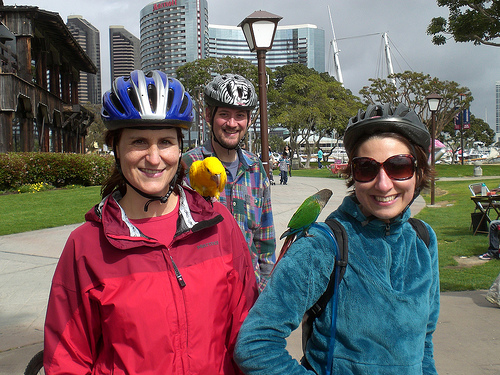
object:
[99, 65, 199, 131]
helmet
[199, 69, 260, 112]
helmet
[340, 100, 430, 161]
helmet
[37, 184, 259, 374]
jacket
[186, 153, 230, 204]
bird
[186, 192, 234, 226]
shoulder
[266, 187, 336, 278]
bird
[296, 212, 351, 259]
shoulder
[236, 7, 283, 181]
lamp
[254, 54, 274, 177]
post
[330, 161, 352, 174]
table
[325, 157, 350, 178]
picnic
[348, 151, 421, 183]
sunglasses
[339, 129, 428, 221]
head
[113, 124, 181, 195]
head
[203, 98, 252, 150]
head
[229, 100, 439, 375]
woman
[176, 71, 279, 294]
man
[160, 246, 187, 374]
zipper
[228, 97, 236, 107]
black stripes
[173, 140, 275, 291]
shirt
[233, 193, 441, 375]
jacket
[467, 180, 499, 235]
chair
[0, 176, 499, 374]
road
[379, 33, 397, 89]
mast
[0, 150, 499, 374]
park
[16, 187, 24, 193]
flowers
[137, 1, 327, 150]
building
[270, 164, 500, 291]
grass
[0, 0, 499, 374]
background